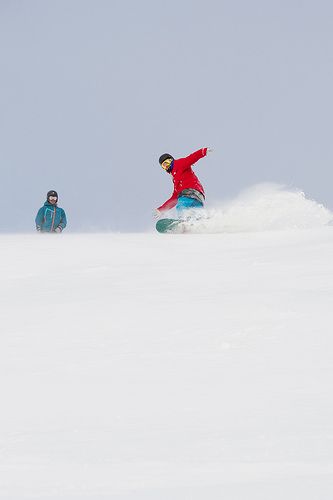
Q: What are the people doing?
A: Snowboarding.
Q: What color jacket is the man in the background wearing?
A: Blue.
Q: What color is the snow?
A: White.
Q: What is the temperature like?
A: Cold.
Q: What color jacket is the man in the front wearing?
A: Red.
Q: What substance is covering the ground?
A: Snow.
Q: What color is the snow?
A: White.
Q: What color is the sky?
A: Gray.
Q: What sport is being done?
A: Snowboarding.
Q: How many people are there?
A: Two.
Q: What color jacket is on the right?
A: Red.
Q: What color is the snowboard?
A: Green.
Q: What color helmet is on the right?
A: Black.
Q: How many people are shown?
A: 2.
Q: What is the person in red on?
A: Snowboard.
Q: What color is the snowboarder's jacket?
A: Red.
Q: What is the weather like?
A: Cold with snow.